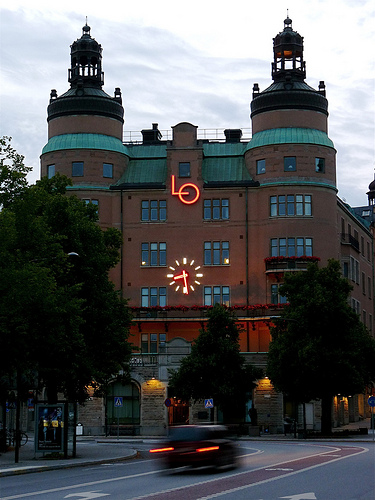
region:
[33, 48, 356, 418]
the building is orange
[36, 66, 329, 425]
the building is orange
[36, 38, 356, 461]
the building is orange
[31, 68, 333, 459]
the building is orange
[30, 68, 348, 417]
the building is orange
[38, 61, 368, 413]
the building is orange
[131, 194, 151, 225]
Small window on a large building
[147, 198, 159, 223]
Small window on a large building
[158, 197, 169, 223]
Small window on a large building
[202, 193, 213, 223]
Small window on a large building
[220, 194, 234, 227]
Small window on a large building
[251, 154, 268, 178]
Small window on a large building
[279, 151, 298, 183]
Small window on a large building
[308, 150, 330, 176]
Small window on a large building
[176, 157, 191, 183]
Small window on a large building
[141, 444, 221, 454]
lights trailing the car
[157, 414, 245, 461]
red vehicle on the road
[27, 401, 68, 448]
blue border on large poster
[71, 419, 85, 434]
white trash can on the sidewalk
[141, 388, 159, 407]
black and white bricks on the wall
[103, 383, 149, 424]
green drapes in window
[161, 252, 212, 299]
lighted yellow clock on wall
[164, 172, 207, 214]
large orange logo on wall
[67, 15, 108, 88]
tall steeple on top of building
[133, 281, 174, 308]
Window of a building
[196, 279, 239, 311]
Window of a building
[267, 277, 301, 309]
Window of a building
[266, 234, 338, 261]
Window of a building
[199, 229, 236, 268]
Window of a building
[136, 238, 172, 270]
Window of a building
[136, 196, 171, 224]
Window of a building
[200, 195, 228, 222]
Window of a building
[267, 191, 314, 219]
Window of a building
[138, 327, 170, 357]
Window of a building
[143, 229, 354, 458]
trees in front of the building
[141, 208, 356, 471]
trees in front of the building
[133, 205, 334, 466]
trees in front of the building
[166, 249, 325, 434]
trees in front of the building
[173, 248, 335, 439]
trees in front of the building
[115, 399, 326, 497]
the street is paved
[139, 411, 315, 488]
the street is paved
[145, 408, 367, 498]
the street is paved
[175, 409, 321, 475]
the street is paved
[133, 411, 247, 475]
A moving vehicle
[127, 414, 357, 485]
A vehicle on a road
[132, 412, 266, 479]
A moving car